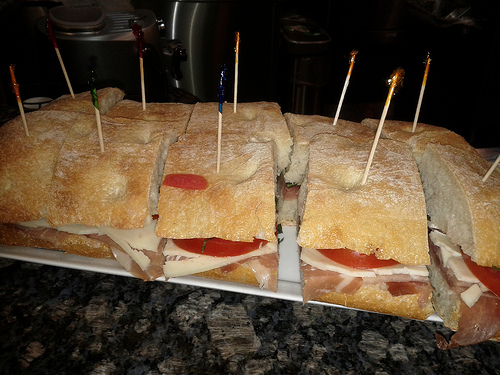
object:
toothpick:
[214, 56, 227, 175]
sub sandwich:
[156, 130, 281, 294]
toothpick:
[359, 66, 405, 189]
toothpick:
[82, 49, 105, 153]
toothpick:
[128, 16, 147, 110]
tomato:
[172, 237, 271, 259]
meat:
[218, 252, 278, 283]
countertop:
[0, 258, 499, 373]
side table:
[265, 12, 351, 119]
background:
[13, 6, 494, 113]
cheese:
[163, 239, 275, 278]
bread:
[153, 128, 280, 244]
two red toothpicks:
[47, 39, 148, 111]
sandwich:
[2, 85, 499, 344]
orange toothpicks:
[410, 51, 433, 135]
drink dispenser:
[154, 4, 241, 110]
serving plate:
[0, 211, 498, 326]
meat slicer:
[35, 13, 169, 65]